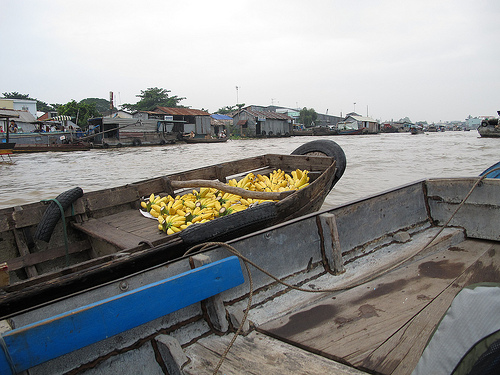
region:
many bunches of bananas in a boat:
[147, 163, 299, 238]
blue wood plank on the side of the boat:
[19, 246, 248, 364]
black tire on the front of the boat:
[291, 133, 348, 173]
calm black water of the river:
[66, 158, 151, 175]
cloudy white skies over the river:
[253, 0, 368, 90]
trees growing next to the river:
[4, 91, 165, 128]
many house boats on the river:
[15, 94, 363, 151]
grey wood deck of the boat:
[313, 279, 401, 348]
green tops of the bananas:
[157, 217, 172, 229]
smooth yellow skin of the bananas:
[248, 173, 282, 191]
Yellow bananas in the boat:
[132, 163, 326, 241]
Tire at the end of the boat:
[278, 135, 354, 194]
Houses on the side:
[0, 90, 481, 150]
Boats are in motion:
[11, 86, 498, 366]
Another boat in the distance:
[468, 105, 499, 147]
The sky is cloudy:
[31, 7, 482, 101]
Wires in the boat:
[23, 193, 100, 278]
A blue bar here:
[2, 276, 292, 348]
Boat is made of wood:
[28, 127, 498, 357]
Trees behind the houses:
[47, 78, 190, 145]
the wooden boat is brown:
[41, 138, 286, 313]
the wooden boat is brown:
[27, 122, 411, 270]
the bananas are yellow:
[147, 143, 348, 286]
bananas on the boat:
[141, 153, 336, 231]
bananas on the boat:
[124, 126, 395, 295]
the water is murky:
[347, 108, 447, 207]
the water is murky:
[13, 131, 155, 183]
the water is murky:
[55, 136, 187, 209]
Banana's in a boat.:
[135, 166, 315, 236]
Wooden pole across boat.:
[177, 178, 289, 198]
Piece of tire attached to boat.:
[32, 188, 79, 242]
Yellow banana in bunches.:
[137, 163, 308, 235]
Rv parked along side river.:
[103, 119, 177, 147]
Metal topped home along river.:
[235, 105, 290, 137]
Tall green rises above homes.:
[125, 85, 184, 114]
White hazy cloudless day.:
[246, 27, 438, 87]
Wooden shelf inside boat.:
[63, 205, 155, 247]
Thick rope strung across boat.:
[190, 237, 374, 365]